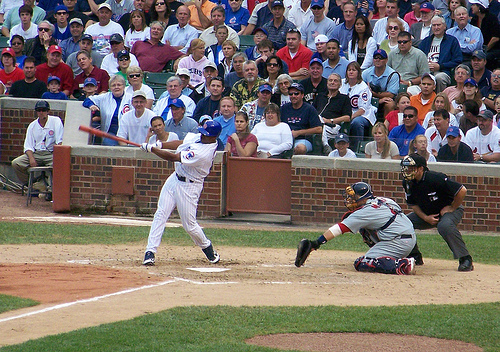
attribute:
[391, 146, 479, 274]
umpire — squatting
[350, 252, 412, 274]
guard — black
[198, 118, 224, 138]
helmet — hard, blue, protective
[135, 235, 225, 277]
shoes — black, white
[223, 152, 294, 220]
gate — brown, metal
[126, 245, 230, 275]
shoes — black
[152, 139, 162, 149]
baseball glove — white, small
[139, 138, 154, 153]
baseball glove — white, small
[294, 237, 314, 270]
glove — black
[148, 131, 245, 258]
uniform — white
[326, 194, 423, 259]
baseball uniform — grey, red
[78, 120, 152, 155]
bat — red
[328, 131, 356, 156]
boy — young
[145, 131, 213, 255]
uniform — white